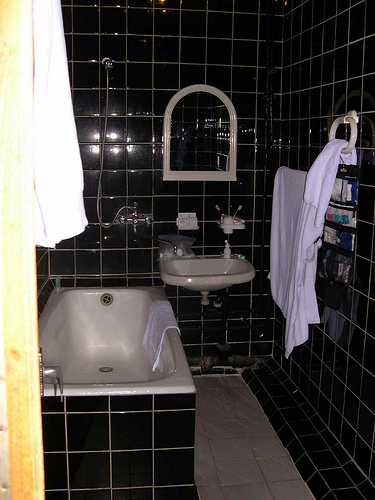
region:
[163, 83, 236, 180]
Mirror on wall in bathroom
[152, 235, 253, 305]
Sink on wall in bathroom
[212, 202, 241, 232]
Toothbrush holder on wall in bathroom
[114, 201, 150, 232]
Water controls for tub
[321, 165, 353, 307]
Travel kit of toiletries hanging on wall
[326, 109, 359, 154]
Ring to hold towels on wall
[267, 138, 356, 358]
Towels hanging on towel holders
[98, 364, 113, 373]
Drain in bath tub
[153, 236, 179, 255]
Handle for sink water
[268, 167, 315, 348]
A white towel on a rack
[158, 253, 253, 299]
A white sink in a bathroom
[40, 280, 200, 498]
A bathtub in a small bathroom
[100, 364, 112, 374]
A drain in a bathtub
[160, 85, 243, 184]
A mirror on a bathroom wall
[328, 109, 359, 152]
A white ring towel holder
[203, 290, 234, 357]
Water pipes under a sink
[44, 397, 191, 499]
Black tile on a bathtub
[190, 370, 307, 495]
Cloth on a tile floor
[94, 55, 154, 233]
Metal fixtures for a sink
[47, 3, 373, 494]
shiny black ceramic walls in bathroom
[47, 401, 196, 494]
black ceramic tile surrounding tub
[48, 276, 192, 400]
white porcelain tub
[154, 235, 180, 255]
silver water faucet over sink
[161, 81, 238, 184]
bathroom mirror with white frame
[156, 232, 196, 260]
plastic bag on top of sink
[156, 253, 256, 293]
white wall mounted sink basin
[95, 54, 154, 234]
silver shower head and knobs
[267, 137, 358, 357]
white bath and hand towel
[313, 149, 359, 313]
black organizer hanging on a hanger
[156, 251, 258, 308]
white sink in bathroom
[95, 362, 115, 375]
drain at bottom of white bath tub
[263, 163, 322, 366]
white towel on rack in bathroom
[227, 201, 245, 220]
toothbrush in bathroom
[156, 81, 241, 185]
mirror over sink in bathroom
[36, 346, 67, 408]
metal handle on door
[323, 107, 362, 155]
plastic towel ring holder on wall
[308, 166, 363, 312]
plastic compartment storage device on wall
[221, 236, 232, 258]
white bottle on edge of sink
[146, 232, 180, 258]
silver sink faucet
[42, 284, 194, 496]
white bathtub with black tile on the outside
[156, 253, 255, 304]
small white sink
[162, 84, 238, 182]
small mirror framed in white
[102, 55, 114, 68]
silver shower head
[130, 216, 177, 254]
silver sink faucet connected to the water line for the shower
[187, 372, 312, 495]
white tile on the floor